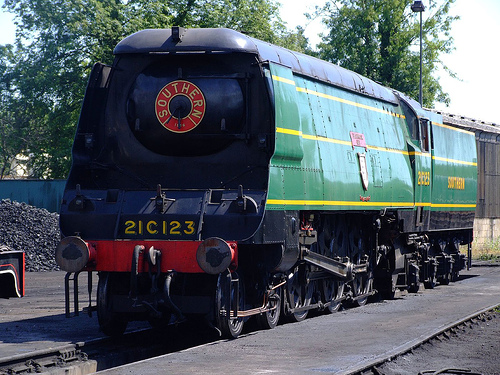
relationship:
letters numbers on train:
[121, 217, 197, 236] [52, 23, 482, 340]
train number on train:
[115, 215, 195, 237] [99, 11, 494, 313]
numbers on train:
[120, 219, 196, 236] [52, 23, 482, 340]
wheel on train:
[207, 277, 258, 342] [62, 19, 499, 364]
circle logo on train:
[146, 70, 221, 142] [46, 15, 489, 319]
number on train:
[122, 214, 197, 241] [52, 23, 482, 340]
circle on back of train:
[153, 77, 205, 132] [52, 23, 482, 340]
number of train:
[120, 216, 199, 236] [62, 32, 492, 307]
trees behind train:
[6, 18, 467, 184] [52, 23, 482, 340]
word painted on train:
[444, 173, 465, 189] [52, 23, 482, 340]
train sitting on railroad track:
[52, 23, 482, 340] [1, 323, 226, 373]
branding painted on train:
[447, 176, 464, 190] [84, 30, 494, 337]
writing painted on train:
[415, 166, 432, 186] [84, 30, 494, 337]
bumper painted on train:
[56, 235, 239, 274] [52, 23, 482, 340]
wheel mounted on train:
[216, 293, 246, 341] [46, 15, 489, 319]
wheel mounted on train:
[257, 276, 281, 330] [46, 15, 489, 319]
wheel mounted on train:
[282, 260, 315, 322] [46, 15, 489, 319]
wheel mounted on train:
[318, 218, 347, 313] [46, 15, 489, 319]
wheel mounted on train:
[349, 218, 377, 306] [46, 15, 489, 319]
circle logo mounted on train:
[154, 80, 206, 133] [52, 23, 482, 340]